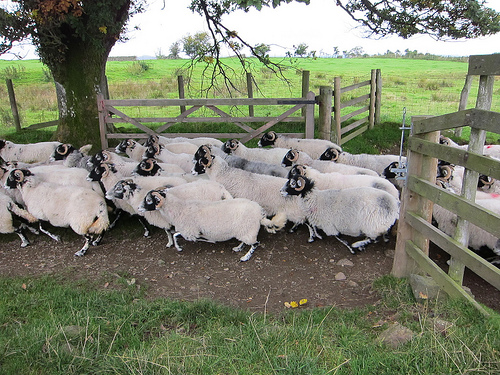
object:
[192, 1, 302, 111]
branches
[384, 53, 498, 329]
fence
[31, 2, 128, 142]
tree trunk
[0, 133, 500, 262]
herd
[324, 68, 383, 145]
gate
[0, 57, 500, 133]
field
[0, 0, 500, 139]
large tree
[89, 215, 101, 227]
yellow spot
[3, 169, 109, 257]
sheep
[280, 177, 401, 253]
sheep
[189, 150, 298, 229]
sheep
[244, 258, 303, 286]
dirt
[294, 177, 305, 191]
horn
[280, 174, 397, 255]
ram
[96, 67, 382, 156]
fence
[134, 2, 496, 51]
sky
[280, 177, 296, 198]
faces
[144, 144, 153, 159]
faces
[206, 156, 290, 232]
sheep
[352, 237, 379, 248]
leg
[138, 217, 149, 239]
leg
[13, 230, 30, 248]
leg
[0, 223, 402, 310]
trail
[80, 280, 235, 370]
grass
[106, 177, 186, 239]
sheep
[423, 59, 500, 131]
grass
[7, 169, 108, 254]
ram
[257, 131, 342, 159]
sheep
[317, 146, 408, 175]
sheep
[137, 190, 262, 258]
sheep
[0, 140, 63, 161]
rams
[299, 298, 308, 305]
flowers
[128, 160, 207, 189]
sheep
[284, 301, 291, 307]
flowers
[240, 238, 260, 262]
leg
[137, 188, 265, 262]
ram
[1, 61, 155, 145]
grass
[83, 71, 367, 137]
posts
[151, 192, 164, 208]
horns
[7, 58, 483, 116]
pasture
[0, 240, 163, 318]
dirt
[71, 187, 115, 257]
butt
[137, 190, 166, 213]
head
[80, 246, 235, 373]
ground